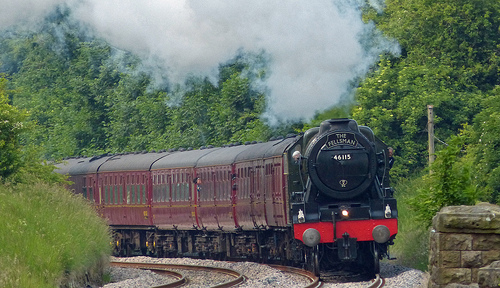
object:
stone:
[399, 281, 406, 283]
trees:
[0, 74, 76, 187]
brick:
[472, 233, 499, 250]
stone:
[238, 265, 248, 270]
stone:
[431, 267, 472, 283]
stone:
[476, 267, 500, 288]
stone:
[242, 262, 249, 267]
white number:
[341, 154, 343, 160]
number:
[334, 154, 339, 161]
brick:
[437, 232, 471, 249]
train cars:
[96, 150, 170, 260]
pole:
[425, 103, 435, 176]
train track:
[110, 260, 247, 288]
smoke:
[0, 0, 402, 138]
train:
[42, 117, 399, 280]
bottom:
[293, 218, 399, 245]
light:
[341, 209, 349, 218]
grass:
[0, 176, 113, 288]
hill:
[0, 74, 111, 287]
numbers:
[347, 153, 352, 160]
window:
[183, 182, 189, 201]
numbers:
[337, 154, 342, 160]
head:
[191, 176, 201, 185]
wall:
[428, 202, 500, 288]